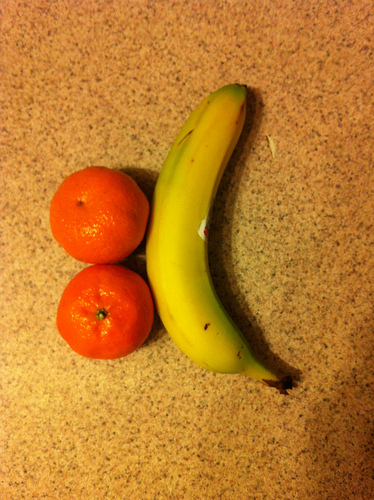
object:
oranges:
[47, 164, 156, 360]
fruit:
[144, 82, 293, 402]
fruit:
[44, 160, 149, 263]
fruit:
[56, 262, 153, 362]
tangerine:
[53, 268, 148, 360]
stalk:
[252, 367, 299, 388]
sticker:
[197, 211, 211, 243]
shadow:
[296, 347, 370, 498]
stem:
[246, 357, 295, 394]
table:
[55, 64, 153, 143]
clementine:
[57, 266, 156, 366]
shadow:
[204, 87, 300, 384]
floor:
[0, 0, 372, 498]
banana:
[142, 83, 291, 398]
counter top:
[0, 0, 374, 500]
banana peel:
[195, 151, 212, 201]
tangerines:
[47, 165, 152, 360]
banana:
[154, 84, 272, 402]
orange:
[43, 168, 149, 264]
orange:
[56, 262, 148, 351]